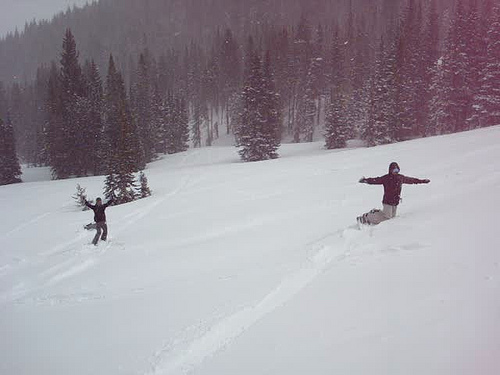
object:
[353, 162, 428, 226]
person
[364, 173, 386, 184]
arm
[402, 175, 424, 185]
arm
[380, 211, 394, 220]
knees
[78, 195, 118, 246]
person standing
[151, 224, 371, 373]
trail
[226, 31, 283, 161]
pine trees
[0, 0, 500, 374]
background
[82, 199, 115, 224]
coat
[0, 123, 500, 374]
flat snow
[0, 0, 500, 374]
hill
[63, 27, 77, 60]
top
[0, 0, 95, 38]
dark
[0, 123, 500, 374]
ground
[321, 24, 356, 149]
trees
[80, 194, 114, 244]
person in distance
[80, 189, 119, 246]
uphill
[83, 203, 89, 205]
hands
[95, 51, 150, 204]
large tree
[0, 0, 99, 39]
sky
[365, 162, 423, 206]
jacket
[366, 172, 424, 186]
arms out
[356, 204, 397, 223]
pants are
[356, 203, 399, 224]
in color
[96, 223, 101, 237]
khaki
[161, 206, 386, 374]
person made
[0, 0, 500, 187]
forest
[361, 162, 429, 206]
black jacket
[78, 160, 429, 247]
two